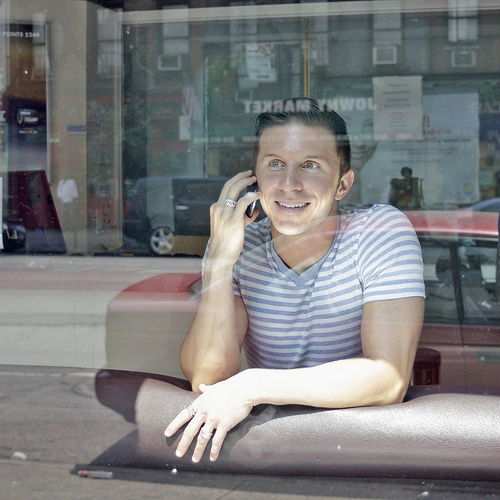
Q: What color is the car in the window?
A: Red.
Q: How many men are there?
A: 1.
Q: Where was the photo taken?
A: Restaurant.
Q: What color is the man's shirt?
A: Striped.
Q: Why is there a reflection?
A: Glass.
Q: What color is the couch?
A: Brown.